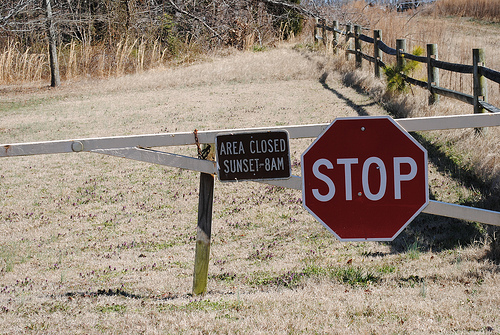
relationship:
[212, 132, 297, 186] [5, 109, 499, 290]
sign on railing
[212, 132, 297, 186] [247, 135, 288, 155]
sign says closed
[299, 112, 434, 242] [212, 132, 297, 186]
stop sign next to sign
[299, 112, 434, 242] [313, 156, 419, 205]
sign says stop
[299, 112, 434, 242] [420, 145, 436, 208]
sign has sides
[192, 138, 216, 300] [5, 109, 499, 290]
post attached to railings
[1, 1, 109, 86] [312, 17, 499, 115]
pine near fence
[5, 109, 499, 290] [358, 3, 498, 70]
railings for pasture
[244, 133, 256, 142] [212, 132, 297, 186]
screw in sign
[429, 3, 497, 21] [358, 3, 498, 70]
bushes are in field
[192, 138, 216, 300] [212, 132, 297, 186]
post holding up sign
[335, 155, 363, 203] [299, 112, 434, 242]
t on stop sign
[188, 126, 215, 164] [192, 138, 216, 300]
chain connects post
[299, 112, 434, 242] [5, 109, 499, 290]
stop sign bolted to fence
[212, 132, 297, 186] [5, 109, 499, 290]
sign on railings